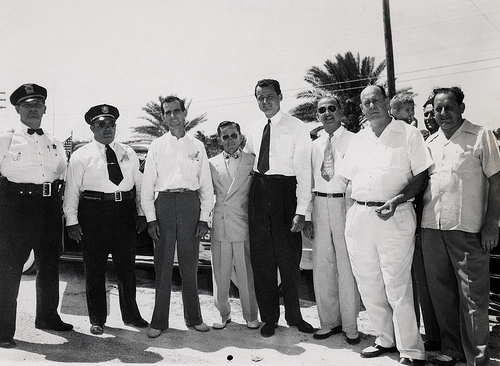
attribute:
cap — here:
[13, 87, 47, 100]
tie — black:
[100, 142, 130, 185]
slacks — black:
[240, 164, 306, 322]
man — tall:
[243, 64, 315, 345]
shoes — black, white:
[86, 309, 151, 339]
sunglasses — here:
[91, 118, 118, 129]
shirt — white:
[327, 117, 436, 211]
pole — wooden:
[372, 0, 405, 92]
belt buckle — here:
[325, 191, 334, 199]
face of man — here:
[91, 118, 117, 140]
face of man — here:
[23, 96, 44, 119]